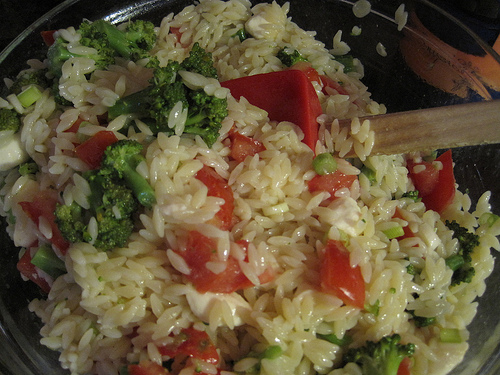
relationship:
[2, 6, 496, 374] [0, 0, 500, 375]
bowl full of bowl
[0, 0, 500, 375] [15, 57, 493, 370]
rice in bowl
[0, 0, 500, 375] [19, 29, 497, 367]
rice in bowl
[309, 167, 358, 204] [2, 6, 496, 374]
pepper in bowl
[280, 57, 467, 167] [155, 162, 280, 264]
spatula in rice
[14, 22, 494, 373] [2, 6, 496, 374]
rice in bowl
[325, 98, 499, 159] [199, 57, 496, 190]
handle on spatula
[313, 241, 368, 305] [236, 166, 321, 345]
tomato next to rice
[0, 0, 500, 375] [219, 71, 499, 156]
rice on spatula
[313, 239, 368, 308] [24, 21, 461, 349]
tomato on rice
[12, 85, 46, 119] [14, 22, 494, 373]
celery in rice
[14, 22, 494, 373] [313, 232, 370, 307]
rice in a bowl with broccoli and pepper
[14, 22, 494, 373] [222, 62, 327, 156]
rice in a bowl with broccoli and pepper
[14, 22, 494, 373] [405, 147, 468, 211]
rice in a bowl with broccoli and pepper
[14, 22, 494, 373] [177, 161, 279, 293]
rice in a bowl with broccoli and peppers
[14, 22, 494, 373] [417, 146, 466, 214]
rice in a bowl with broccoli and pepper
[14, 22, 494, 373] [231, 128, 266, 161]
rice in a bowl with broccoli and pepper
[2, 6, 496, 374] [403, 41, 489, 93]
bowl made of glass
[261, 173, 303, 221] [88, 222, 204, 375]
grains of rice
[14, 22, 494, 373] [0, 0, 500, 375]
rice on bowl